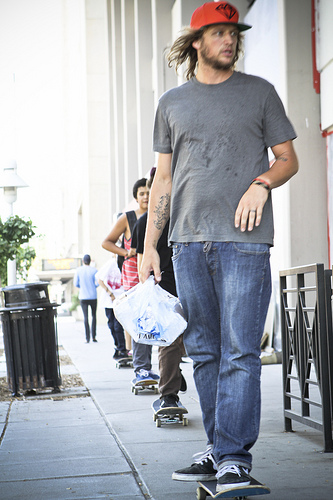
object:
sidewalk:
[0, 314, 332, 497]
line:
[104, 0, 117, 225]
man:
[128, 161, 195, 411]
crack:
[87, 388, 156, 498]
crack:
[5, 468, 137, 487]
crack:
[0, 393, 17, 444]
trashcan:
[0, 278, 65, 397]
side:
[0, 315, 58, 397]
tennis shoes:
[171, 442, 217, 484]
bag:
[111, 271, 192, 350]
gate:
[279, 261, 332, 454]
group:
[98, 0, 300, 495]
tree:
[0, 212, 42, 294]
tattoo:
[151, 191, 172, 235]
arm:
[143, 100, 183, 254]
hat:
[189, 0, 253, 35]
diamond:
[215, 0, 240, 23]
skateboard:
[191, 462, 271, 498]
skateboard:
[150, 393, 190, 429]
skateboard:
[129, 367, 163, 397]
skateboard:
[113, 351, 135, 370]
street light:
[0, 148, 29, 217]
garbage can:
[0, 278, 65, 394]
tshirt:
[150, 68, 299, 252]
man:
[137, 0, 301, 490]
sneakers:
[211, 449, 252, 494]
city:
[0, 0, 332, 498]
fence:
[277, 260, 333, 452]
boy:
[100, 175, 162, 383]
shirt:
[120, 207, 154, 293]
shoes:
[133, 364, 157, 386]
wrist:
[249, 176, 276, 195]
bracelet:
[252, 175, 272, 200]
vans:
[194, 450, 273, 498]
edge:
[0, 386, 91, 403]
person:
[73, 249, 102, 344]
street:
[0, 303, 332, 498]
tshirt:
[74, 262, 101, 304]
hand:
[134, 246, 166, 293]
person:
[130, 167, 192, 412]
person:
[97, 243, 136, 361]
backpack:
[117, 210, 153, 275]